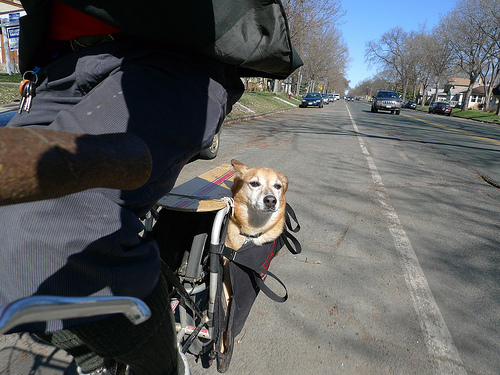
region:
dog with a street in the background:
[211, 147, 298, 262]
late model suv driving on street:
[363, 78, 413, 122]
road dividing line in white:
[306, 21, 492, 372]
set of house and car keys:
[5, 62, 53, 124]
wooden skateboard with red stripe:
[135, 144, 270, 231]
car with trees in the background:
[295, 87, 329, 114]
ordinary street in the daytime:
[236, 8, 493, 370]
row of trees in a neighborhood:
[353, 0, 498, 147]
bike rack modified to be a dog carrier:
[176, 144, 321, 374]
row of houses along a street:
[346, 6, 496, 146]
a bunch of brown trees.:
[361, 0, 498, 87]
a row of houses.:
[409, 72, 499, 107]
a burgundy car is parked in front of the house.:
[419, 91, 460, 124]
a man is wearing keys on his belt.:
[2, 57, 52, 119]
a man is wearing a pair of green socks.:
[105, 302, 175, 366]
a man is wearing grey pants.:
[136, 72, 200, 119]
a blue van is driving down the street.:
[362, 64, 417, 130]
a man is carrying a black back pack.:
[156, 0, 313, 84]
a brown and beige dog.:
[217, 150, 294, 290]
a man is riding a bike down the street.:
[3, 0, 324, 374]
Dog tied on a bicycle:
[223, 155, 288, 366]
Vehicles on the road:
[298, 90, 433, 105]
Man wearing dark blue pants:
[1, 49, 228, 309]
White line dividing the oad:
[346, 95, 471, 374]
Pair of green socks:
[50, 283, 180, 374]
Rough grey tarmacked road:
[216, 120, 498, 369]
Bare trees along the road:
[352, 4, 498, 118]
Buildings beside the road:
[421, 76, 498, 111]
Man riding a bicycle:
[2, 2, 260, 359]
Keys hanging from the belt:
[18, 65, 43, 121]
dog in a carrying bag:
[223, 160, 296, 263]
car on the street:
[367, 88, 409, 118]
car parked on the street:
[296, 88, 328, 113]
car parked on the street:
[426, 100, 457, 116]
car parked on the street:
[320, 89, 332, 107]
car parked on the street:
[326, 90, 339, 105]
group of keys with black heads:
[7, 65, 47, 117]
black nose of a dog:
[262, 192, 277, 207]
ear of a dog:
[230, 154, 248, 180]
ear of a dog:
[277, 168, 289, 194]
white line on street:
[355, 161, 383, 221]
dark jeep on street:
[371, 87, 407, 123]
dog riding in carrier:
[241, 170, 307, 244]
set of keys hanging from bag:
[4, 60, 41, 118]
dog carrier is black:
[224, 257, 241, 304]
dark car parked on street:
[303, 93, 312, 120]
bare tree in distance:
[466, 62, 486, 89]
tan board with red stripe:
[193, 188, 203, 205]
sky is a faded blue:
[371, 16, 411, 49]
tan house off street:
[465, 92, 495, 124]